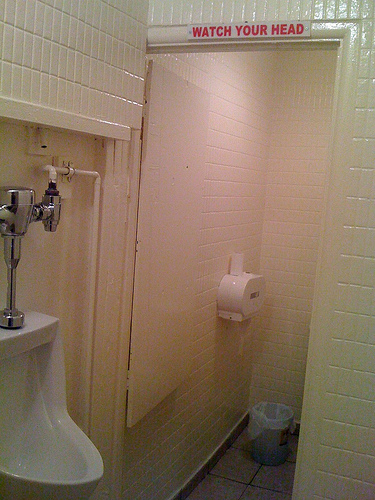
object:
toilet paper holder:
[215, 272, 265, 320]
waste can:
[0, 0, 375, 500]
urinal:
[0, 307, 105, 500]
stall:
[108, 17, 362, 500]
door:
[126, 59, 209, 427]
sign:
[187, 19, 312, 43]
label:
[292, 421, 299, 433]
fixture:
[0, 182, 62, 330]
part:
[221, 86, 321, 245]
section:
[157, 92, 203, 164]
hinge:
[126, 374, 134, 401]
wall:
[218, 122, 374, 492]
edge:
[300, 20, 363, 423]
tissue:
[224, 322, 246, 358]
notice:
[191, 23, 304, 38]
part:
[245, 5, 311, 52]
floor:
[205, 477, 291, 500]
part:
[229, 431, 255, 456]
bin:
[251, 401, 294, 467]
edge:
[250, 401, 295, 423]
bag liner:
[246, 400, 297, 443]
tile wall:
[208, 147, 256, 239]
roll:
[250, 419, 294, 448]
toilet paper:
[227, 239, 268, 286]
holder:
[216, 271, 267, 322]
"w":
[190, 25, 200, 37]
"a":
[202, 27, 210, 39]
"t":
[209, 27, 215, 38]